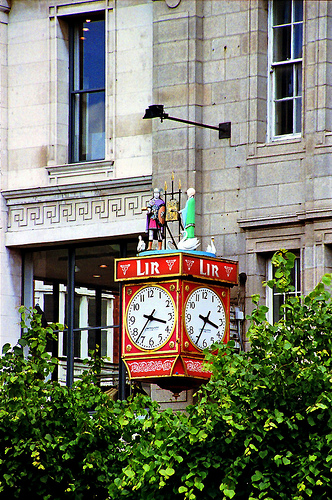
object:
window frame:
[264, 0, 305, 143]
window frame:
[65, 16, 108, 164]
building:
[0, 6, 331, 380]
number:
[128, 315, 136, 326]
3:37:
[123, 300, 171, 345]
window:
[66, 17, 103, 165]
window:
[263, 250, 302, 362]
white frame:
[264, 259, 276, 335]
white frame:
[274, 291, 297, 295]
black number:
[139, 292, 145, 305]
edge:
[114, 285, 127, 362]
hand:
[141, 311, 167, 325]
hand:
[134, 307, 157, 344]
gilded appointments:
[112, 168, 241, 386]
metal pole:
[148, 380, 205, 418]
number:
[202, 291, 209, 300]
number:
[210, 295, 215, 302]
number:
[147, 338, 154, 346]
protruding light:
[141, 103, 231, 139]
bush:
[0, 305, 118, 500]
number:
[188, 325, 194, 333]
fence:
[26, 268, 122, 415]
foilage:
[275, 412, 284, 425]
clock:
[116, 277, 233, 357]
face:
[112, 244, 238, 386]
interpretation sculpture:
[130, 170, 206, 251]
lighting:
[98, 262, 108, 270]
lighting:
[91, 271, 102, 282]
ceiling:
[4, 241, 112, 288]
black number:
[167, 311, 173, 321]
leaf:
[271, 406, 284, 426]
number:
[131, 301, 140, 311]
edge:
[65, 36, 74, 162]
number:
[165, 310, 174, 320]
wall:
[0, 1, 332, 177]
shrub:
[1, 303, 66, 414]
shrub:
[109, 407, 212, 498]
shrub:
[192, 246, 332, 441]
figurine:
[144, 186, 167, 250]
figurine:
[135, 232, 146, 252]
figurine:
[176, 186, 197, 252]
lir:
[135, 257, 161, 277]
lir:
[198, 258, 221, 279]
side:
[111, 255, 179, 380]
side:
[179, 251, 236, 377]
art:
[133, 167, 202, 253]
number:
[145, 288, 152, 298]